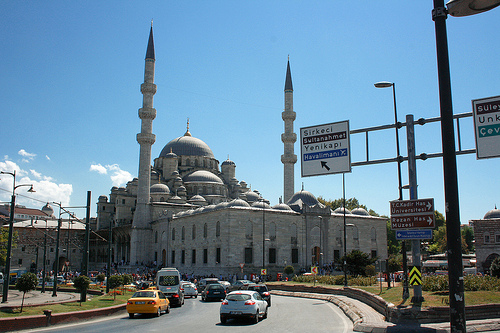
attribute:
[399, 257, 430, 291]
sign — yellow, black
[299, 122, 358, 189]
sign — non english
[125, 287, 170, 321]
cab — yellow, taxi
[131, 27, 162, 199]
building — tall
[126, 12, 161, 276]
tower — tall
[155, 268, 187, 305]
bus — small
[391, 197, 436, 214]
sign — traffic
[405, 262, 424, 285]
sign — yellow, black, traffic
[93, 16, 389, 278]
building — large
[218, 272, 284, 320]
car — white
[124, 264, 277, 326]
cars — many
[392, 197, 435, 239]
sign — illegible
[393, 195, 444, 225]
sign — brown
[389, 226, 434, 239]
sign — blue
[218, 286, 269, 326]
car — stalled, white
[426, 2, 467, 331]
pole — black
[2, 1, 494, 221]
sky — clear, blue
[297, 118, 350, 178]
wall — small